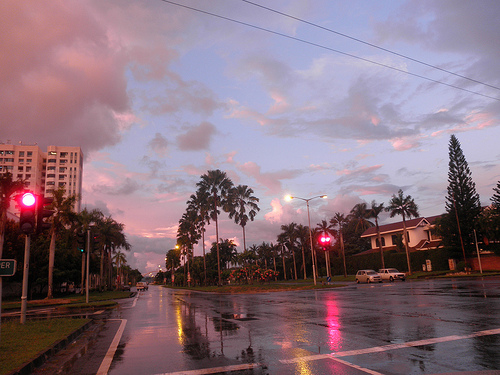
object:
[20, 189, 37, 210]
light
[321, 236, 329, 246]
light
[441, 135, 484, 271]
tree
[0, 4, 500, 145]
sky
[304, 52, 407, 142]
clouds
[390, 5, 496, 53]
clouds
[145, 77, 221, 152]
clouds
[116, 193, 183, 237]
clouds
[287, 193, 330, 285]
light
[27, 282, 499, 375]
street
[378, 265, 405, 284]
car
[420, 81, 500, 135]
clouds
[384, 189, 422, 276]
tree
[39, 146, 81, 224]
building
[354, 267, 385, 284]
car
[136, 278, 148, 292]
car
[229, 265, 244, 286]
plant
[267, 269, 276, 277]
flowers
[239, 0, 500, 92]
cables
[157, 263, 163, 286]
lights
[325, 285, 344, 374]
reflection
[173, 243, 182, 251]
light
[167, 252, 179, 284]
light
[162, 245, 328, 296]
island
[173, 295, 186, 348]
reflection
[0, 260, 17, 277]
sign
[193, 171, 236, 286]
group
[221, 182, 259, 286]
tree